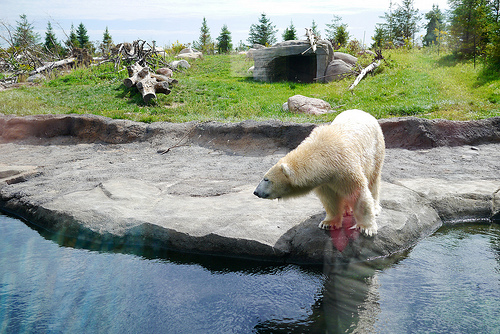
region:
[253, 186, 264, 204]
Bear has black nose.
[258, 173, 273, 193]
Bear has dark eye.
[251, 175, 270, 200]
Bear has white face.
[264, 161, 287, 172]
Bear has white head.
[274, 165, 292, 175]
Bear has white ear.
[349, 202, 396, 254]
Bear has white paw.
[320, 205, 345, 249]
Bear has white paw.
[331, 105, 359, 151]
Bear has white back.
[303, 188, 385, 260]
Bear is standing on rocky ground.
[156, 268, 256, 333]
Water in front of bear.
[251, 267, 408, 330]
The reflection of a polar bear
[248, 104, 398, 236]
A polar bear looking to its right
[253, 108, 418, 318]
A polar bear standing near water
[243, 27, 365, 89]
Man made cave in the hill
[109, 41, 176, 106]
Part of a dead tree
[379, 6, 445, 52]
Sporadic green trees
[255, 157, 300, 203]
Left side of a polar bears face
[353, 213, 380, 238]
Left foot of a polar bear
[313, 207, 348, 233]
Right foot of a polar bear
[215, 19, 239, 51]
An evergreen tree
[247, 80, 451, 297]
this is a polar bear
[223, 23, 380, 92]
a man-made cave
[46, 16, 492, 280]
the bear is behind a glass window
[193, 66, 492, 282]
this is a white polar bear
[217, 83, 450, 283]
the bear is next to the water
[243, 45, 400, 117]
the cave is dark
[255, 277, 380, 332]
reflection of the polar bear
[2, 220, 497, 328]
the surface of the water looks cool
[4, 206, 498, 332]
the surface of the water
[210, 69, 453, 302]
a polar bear standing on a rock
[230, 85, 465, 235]
here is a polar bear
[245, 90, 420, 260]
a white polar bear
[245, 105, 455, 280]
a polar bear in a zoo exhibit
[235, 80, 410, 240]
the polar bear is white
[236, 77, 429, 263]
the polar bear has white fur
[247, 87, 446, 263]
the polar bear is at the edge of the water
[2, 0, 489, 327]
you can see reflections from the glass window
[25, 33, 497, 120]
a small grassy hill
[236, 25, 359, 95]
here is a man-made cave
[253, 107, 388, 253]
white polar bear standing up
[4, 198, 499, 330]
water in a polar bear enclosure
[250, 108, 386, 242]
polar bear at the zoo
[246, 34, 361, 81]
a cave for the polar bear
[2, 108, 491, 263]
rocky area next to the water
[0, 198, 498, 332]
water for the polar bear to swim in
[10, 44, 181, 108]
fallen wood laying in grass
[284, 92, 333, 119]
a large rock in the grass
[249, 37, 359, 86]
a small cave in the grass